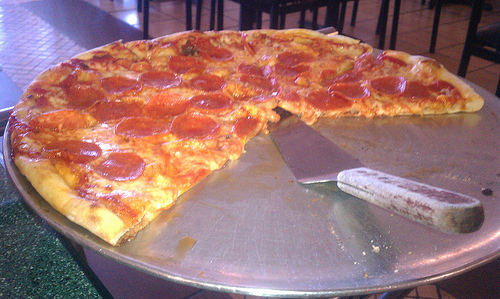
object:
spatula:
[261, 107, 488, 238]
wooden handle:
[330, 166, 486, 242]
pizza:
[5, 26, 487, 246]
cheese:
[113, 54, 417, 113]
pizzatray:
[0, 24, 500, 299]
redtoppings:
[238, 75, 279, 89]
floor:
[0, 0, 139, 99]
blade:
[267, 105, 370, 186]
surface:
[220, 219, 373, 257]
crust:
[443, 73, 485, 113]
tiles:
[45, 27, 55, 33]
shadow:
[61, 15, 124, 31]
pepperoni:
[189, 93, 233, 111]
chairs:
[455, 0, 499, 93]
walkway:
[29, 24, 85, 43]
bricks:
[29, 25, 40, 31]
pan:
[0, 29, 500, 299]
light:
[235, 287, 287, 298]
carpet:
[18, 0, 147, 49]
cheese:
[151, 185, 183, 205]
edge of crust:
[101, 204, 170, 249]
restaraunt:
[0, 0, 500, 299]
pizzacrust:
[40, 191, 66, 215]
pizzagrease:
[241, 164, 279, 208]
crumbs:
[371, 245, 381, 254]